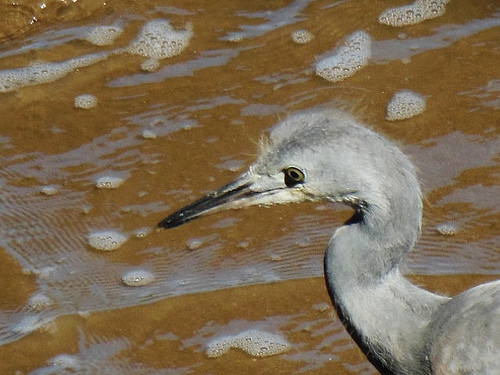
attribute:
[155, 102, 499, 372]
bird — gray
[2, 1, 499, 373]
beach — brown, foamy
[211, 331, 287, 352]
foam — white, ocean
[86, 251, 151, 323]
beach — brown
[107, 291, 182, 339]
beach — brown, ocean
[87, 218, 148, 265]
foam — white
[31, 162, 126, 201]
foam — ocean, white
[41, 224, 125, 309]
beach — brown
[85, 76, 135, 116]
beach — brown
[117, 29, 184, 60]
foam — white, ocean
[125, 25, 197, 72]
foam — ocean, white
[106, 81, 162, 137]
beach — brown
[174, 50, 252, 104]
beach — brown, ocean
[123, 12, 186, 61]
foam — white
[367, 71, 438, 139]
foam — ocean, white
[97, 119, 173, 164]
beach — brown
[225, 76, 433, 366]
bird — grey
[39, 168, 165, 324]
water — shallow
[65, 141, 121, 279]
bubbles — white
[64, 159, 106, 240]
sand — deep , brown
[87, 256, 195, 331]
water — clear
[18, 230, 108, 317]
lines — white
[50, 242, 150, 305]
grids — white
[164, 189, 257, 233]
beak — long, black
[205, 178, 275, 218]
stripes — grey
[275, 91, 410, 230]
feathers — fuzzy , light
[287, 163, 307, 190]
eye — black, yellow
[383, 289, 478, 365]
markings — lighter , gray, circular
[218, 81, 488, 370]
bird — long necked, white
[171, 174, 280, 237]
beak — black, heron's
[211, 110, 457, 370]
bird — gray, white, water bird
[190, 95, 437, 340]
fowl — gray, white, water fowl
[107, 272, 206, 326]
water — shallow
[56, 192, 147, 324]
river bed — dirt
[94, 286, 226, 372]
river bed — dirt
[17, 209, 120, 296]
pattern — cloudy, stripe